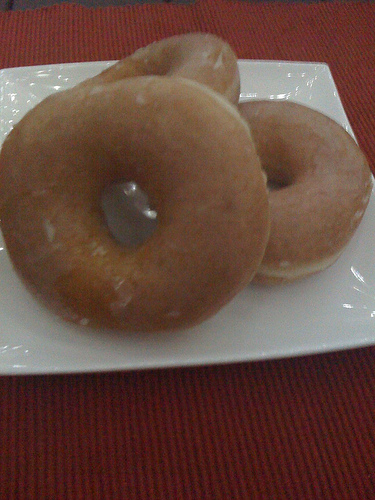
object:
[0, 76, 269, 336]
doughnuts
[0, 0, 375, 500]
mat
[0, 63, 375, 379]
plate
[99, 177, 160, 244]
hole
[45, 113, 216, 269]
middle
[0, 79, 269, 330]
glaze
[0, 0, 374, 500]
table